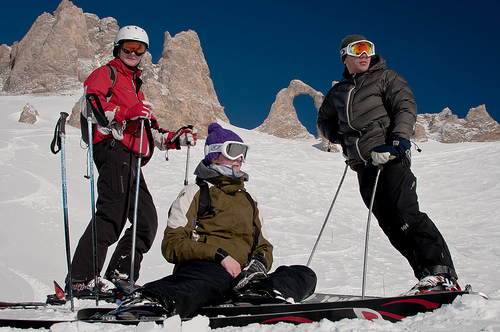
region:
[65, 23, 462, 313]
three skiers in the snow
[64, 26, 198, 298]
skier wearing a red jacket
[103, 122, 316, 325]
skier wearing a purple hat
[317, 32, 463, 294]
skier wearing a black jacket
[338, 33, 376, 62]
white googles on the man in black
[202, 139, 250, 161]
white goggles on the person in the purple hat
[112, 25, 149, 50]
white helmet on the skier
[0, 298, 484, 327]
skies in the snow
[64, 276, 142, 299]
black boots on the person in the red coat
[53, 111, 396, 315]
ski poles in the snow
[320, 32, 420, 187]
man wearing grey jacket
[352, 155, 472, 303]
long black pants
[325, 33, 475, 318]
man wearing black pants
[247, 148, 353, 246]
white snow on the ground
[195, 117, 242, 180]
person wearing purple hat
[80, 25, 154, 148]
person wearing a white helmet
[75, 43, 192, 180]
red snow jacket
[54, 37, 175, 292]
person wearing red jacket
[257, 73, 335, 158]
stone archway in the snow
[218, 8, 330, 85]
clear blue cloudless sky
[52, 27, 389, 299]
people skiing on the snow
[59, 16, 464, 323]
people skiing on a mountain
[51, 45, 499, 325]
people holding ski poles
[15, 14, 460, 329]
two people standing on the snow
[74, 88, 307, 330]
a person sitting on the snow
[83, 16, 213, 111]
a person wearing a helmet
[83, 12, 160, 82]
a person wearing a white helmet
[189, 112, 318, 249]
a person wearing a purple hat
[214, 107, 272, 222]
a person wearing a purple beanie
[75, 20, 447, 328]
skiers wearing jackets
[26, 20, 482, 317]
Guys are snow skiing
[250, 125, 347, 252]
Ground is snow covered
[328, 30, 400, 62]
The man is wearing safety goggles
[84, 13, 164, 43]
The man is wearing a safety helmet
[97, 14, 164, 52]
The safety helmet is white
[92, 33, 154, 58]
The man is wearing safety goggles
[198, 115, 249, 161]
The man is wearing a toboggan hat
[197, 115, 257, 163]
The toboggan hat is purple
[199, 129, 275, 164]
The man is wearing white goggles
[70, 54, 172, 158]
The man is wearing a red jacket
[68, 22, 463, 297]
Three people on snow skis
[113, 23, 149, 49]
Woman wearing a white helmet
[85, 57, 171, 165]
Red, white and black ski jacket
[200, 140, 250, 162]
White snow goggles worn by the woman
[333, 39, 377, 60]
Man wearing snow goggles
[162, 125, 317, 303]
Woman sitting in the snow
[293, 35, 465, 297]
Man standing on snow skis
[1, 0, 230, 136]
Rock formation in back of the skiers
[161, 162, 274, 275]
Brown and white ski jacket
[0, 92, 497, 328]
Snow covering the mountain